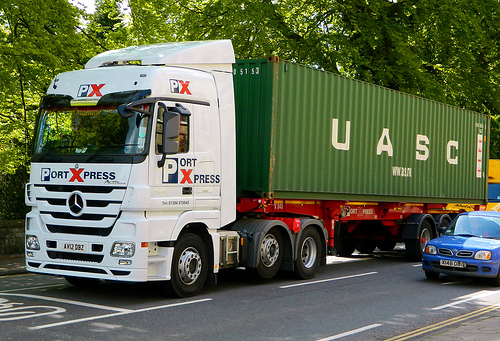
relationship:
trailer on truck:
[225, 18, 499, 275] [251, 93, 469, 200]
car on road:
[416, 201, 498, 290] [8, 261, 495, 339]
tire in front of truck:
[293, 223, 326, 279] [23, 44, 493, 296]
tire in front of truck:
[252, 226, 287, 280] [23, 44, 493, 296]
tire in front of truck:
[169, 234, 211, 299] [23, 44, 493, 296]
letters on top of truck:
[79, 83, 101, 98] [23, 44, 493, 296]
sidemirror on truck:
[148, 107, 195, 152] [24, 29, 346, 291]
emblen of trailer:
[65, 189, 88, 218] [24, 35, 488, 292]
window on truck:
[32, 103, 149, 158] [23, 44, 493, 296]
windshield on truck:
[30, 92, 190, 161] [15, 47, 484, 279]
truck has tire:
[23, 44, 493, 296] [251, 222, 291, 282]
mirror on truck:
[161, 110, 180, 154] [23, 44, 493, 296]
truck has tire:
[23, 44, 493, 296] [404, 219, 436, 259]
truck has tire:
[23, 44, 493, 296] [293, 223, 325, 277]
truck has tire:
[23, 44, 493, 296] [252, 226, 284, 276]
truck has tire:
[23, 44, 493, 296] [173, 234, 211, 287]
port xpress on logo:
[157, 159, 222, 189] [327, 112, 357, 154]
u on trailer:
[329, 115, 354, 152] [246, 52, 486, 195]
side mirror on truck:
[160, 107, 182, 159] [23, 44, 493, 296]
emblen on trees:
[53, 187, 95, 221] [0, 0, 499, 256]